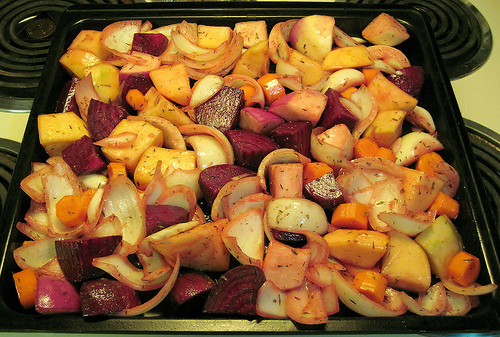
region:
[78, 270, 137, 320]
beets cooking on pan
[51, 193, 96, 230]
carrots cooking in pan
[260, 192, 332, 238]
onion steaming in pan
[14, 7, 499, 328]
pan used to cook is black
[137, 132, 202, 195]
mangos grilling on pan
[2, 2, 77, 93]
electric stove cooking vegetable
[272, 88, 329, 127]
cut up apple on pan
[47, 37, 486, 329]
dish is steaming fruits and vegetable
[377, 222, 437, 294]
apple is green in pan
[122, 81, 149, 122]
cut up orange carrots in pan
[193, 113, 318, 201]
There are beets in the tray.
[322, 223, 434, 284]
There are potatoes in the tray.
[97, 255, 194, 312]
There are onions in the tray.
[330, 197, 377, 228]
There are carrots on the tray.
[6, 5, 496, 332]
The tray contains vegetables.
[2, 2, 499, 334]
The tray sites on a stovetop.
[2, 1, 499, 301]
The stove has four burners.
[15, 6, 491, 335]
The tray is black.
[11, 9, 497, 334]
The tray holds a vegetable mixture.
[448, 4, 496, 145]
The stovetop is yellow.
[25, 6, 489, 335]
dish of roasted vegetables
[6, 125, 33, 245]
front left stove burner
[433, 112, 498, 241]
front right stove burner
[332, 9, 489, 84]
right rear stove burner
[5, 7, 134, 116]
left rear stove burner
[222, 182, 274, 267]
roasted onion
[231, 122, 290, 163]
roasted beet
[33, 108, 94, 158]
a piece of roasted yellow squash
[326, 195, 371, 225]
a piece of roasted carrot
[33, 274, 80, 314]
roasted potato with red skin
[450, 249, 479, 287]
a piece of an orange vegetable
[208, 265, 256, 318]
piece of a red vegetable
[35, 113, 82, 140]
light green piece of a vegetable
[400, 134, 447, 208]
spices on a vegetable dish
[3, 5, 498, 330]
a vegetable dish sitting in a black tray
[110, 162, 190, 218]
pieces of onion sitting among other food items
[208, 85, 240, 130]
wrinkles on the surface of a dark piece of food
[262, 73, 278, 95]
a reflection visible on an orange piece of food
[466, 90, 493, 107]
light green paint on a stovetop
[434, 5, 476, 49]
a dark circular cover on a burner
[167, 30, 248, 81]
A cluster of white onions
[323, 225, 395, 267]
A small piece of potato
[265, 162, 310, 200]
A small piece of carrot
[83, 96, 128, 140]
A small piece of purple potato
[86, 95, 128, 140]
A tiny piece of a purple vegetable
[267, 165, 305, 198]
a tiny piece of an orange vegetable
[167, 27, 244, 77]
Several slivers of onion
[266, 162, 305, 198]
A piece of carrot with spices on it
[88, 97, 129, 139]
A small piece of purple vegetable with spices on it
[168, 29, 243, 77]
tasty onion chunks